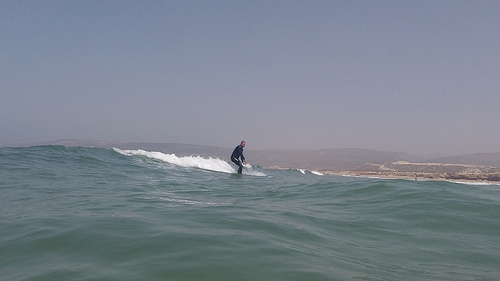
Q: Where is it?
A: This is at the ocean.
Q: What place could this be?
A: It is an ocean.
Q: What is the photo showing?
A: It is showing an ocean.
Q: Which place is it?
A: It is an ocean.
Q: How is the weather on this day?
A: It is cloudless.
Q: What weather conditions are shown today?
A: It is cloudless.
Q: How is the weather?
A: It is cloudless.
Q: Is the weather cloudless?
A: Yes, it is cloudless.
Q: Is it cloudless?
A: Yes, it is cloudless.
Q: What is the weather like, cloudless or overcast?
A: It is cloudless.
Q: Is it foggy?
A: No, it is cloudless.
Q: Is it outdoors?
A: Yes, it is outdoors.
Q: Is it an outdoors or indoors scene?
A: It is outdoors.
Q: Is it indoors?
A: No, it is outdoors.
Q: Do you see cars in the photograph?
A: No, there are no cars.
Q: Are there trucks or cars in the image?
A: No, there are no cars or trucks.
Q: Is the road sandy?
A: Yes, the road is sandy.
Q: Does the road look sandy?
A: Yes, the road is sandy.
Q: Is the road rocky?
A: No, the road is sandy.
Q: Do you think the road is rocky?
A: No, the road is sandy.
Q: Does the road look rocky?
A: No, the road is sandy.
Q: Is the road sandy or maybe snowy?
A: The road is sandy.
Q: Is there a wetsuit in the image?
A: Yes, there is a wetsuit.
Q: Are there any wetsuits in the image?
A: Yes, there is a wetsuit.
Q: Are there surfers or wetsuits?
A: Yes, there is a wetsuit.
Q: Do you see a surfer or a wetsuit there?
A: Yes, there is a wetsuit.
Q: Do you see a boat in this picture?
A: No, there are no boats.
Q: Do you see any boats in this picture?
A: No, there are no boats.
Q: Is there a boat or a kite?
A: No, there are no boats or kites.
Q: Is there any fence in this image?
A: No, there are no fences.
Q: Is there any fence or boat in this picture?
A: No, there are no fences or boats.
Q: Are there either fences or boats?
A: No, there are no fences or boats.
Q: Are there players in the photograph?
A: No, there are no players.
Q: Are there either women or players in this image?
A: No, there are no players or women.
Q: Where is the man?
A: The man is in the ocean.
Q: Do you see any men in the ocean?
A: Yes, there is a man in the ocean.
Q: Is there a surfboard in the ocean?
A: No, there is a man in the ocean.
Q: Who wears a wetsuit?
A: The man wears a wetsuit.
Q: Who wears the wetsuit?
A: The man wears a wetsuit.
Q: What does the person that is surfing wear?
A: The man wears a wet suit.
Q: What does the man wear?
A: The man wears a wet suit.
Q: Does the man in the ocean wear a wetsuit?
A: Yes, the man wears a wetsuit.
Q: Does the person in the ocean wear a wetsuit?
A: Yes, the man wears a wetsuit.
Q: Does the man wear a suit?
A: No, the man wears a wetsuit.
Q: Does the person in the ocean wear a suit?
A: No, the man wears a wetsuit.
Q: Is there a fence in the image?
A: No, there are no fences.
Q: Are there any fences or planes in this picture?
A: No, there are no fences or planes.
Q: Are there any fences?
A: No, there are no fences.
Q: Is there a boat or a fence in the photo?
A: No, there are no fences or boats.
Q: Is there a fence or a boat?
A: No, there are no fences or boats.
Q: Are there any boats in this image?
A: No, there are no boats.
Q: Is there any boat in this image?
A: No, there are no boats.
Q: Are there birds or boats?
A: No, there are no boats or birds.